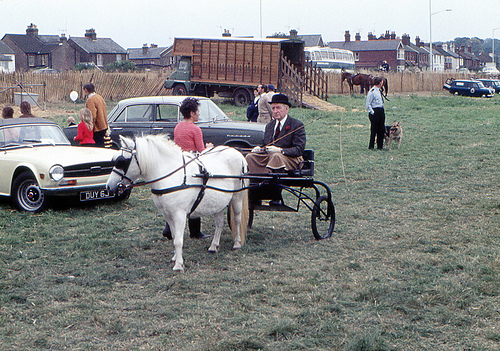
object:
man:
[245, 94, 305, 177]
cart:
[244, 147, 333, 237]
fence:
[0, 64, 498, 104]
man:
[364, 77, 389, 151]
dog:
[378, 120, 405, 150]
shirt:
[74, 121, 96, 145]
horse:
[362, 76, 388, 97]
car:
[55, 85, 268, 151]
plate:
[77, 187, 119, 203]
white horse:
[98, 128, 253, 268]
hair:
[179, 98, 200, 120]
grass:
[411, 212, 493, 289]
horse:
[339, 66, 368, 94]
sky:
[0, 1, 495, 26]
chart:
[215, 194, 343, 248]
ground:
[0, 102, 499, 349]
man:
[79, 81, 108, 149]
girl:
[70, 107, 96, 148]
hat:
[266, 92, 292, 109]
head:
[266, 92, 293, 121]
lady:
[159, 98, 207, 241]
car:
[0, 116, 130, 212]